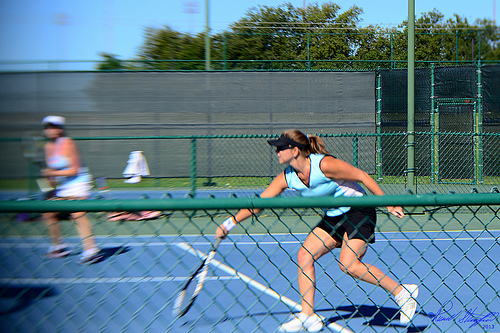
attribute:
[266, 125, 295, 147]
visor — black, dark, small, on, worn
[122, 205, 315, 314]
fence — long, close, green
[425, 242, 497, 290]
court — blue, smooth, light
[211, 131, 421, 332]
woman — active, close, short, playing, white, tan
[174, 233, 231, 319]
racket — black, white